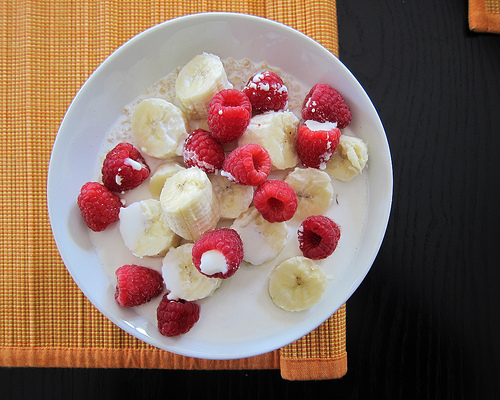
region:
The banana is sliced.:
[159, 164, 229, 236]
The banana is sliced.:
[111, 198, 181, 255]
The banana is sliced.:
[163, 241, 213, 306]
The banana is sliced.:
[265, 254, 333, 316]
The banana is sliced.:
[127, 95, 187, 165]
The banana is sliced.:
[178, 51, 228, 113]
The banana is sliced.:
[237, 106, 301, 166]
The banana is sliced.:
[283, 163, 335, 218]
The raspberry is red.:
[189, 223, 245, 277]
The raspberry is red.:
[108, 250, 158, 312]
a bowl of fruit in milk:
[41, 11, 403, 363]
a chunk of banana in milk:
[156, 166, 231, 234]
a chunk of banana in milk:
[261, 251, 334, 316]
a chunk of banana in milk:
[168, 52, 233, 111]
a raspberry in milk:
[96, 137, 154, 187]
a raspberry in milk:
[205, 84, 252, 138]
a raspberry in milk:
[291, 212, 345, 259]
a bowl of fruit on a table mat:
[2, 2, 408, 396]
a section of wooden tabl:
[401, 61, 487, 399]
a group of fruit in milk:
[124, 85, 291, 290]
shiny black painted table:
[336, 0, 499, 399]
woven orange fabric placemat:
[0, 0, 346, 377]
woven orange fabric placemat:
[468, 0, 499, 31]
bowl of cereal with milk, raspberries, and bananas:
[44, 9, 396, 361]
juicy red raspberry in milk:
[77, 181, 121, 230]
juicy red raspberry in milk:
[113, 263, 165, 309]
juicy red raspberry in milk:
[190, 227, 245, 279]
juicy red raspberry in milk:
[298, 215, 342, 260]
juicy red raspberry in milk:
[294, 118, 341, 167]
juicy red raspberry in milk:
[245, 73, 288, 113]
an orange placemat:
[5, 3, 346, 378]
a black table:
[360, 60, 495, 386]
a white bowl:
[40, 6, 380, 357]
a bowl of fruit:
[62, 10, 387, 342]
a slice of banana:
[270, 256, 325, 303]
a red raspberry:
[230, 145, 270, 181]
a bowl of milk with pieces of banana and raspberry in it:
[62, 20, 362, 345]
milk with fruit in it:
[87, 43, 354, 343]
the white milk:
[213, 293, 269, 334]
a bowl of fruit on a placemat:
[16, 8, 496, 366]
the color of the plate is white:
[41, 14, 413, 364]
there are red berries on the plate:
[110, 261, 167, 307]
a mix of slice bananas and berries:
[101, 88, 319, 287]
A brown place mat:
[11, 11, 80, 88]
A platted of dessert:
[45, 31, 416, 387]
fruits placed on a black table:
[40, 11, 478, 366]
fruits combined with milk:
[108, 90, 343, 321]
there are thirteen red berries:
[71, 83, 375, 335]